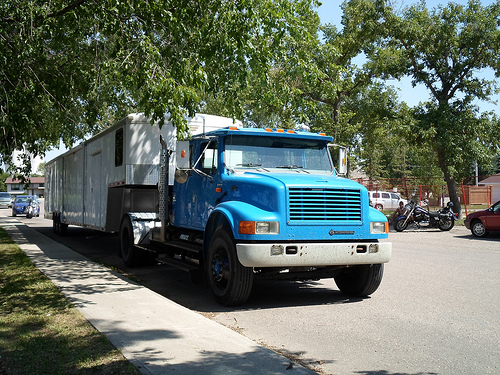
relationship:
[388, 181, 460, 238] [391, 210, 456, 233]
motorcycle has two wheels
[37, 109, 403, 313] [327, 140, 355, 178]
truck has side mirror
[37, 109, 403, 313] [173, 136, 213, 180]
truck has side mirror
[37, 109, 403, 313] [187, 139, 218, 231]
truck has passenger door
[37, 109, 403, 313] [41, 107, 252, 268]
truck has trailer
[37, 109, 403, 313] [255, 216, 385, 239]
truck has headlights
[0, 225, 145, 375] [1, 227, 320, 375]
grass beside sidewalk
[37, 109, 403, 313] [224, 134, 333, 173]
truck has windscreen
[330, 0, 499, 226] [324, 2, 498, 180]
tree has leaves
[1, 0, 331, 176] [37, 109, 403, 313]
leaves hanging above truck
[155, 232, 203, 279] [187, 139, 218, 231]
steps to passenger door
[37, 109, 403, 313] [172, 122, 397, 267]
truck has truck cab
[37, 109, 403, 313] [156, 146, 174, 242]
truck has smokestack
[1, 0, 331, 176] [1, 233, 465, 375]
leaves cast shadow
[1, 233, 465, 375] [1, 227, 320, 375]
shadow on sidewalk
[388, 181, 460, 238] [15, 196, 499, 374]
motorcycle parked on street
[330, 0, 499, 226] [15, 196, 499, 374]
tree beside street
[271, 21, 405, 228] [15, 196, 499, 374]
tree beside street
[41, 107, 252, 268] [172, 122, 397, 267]
trailer attached to truck cab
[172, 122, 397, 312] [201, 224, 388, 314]
truck cab has tires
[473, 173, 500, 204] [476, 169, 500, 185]
house has roof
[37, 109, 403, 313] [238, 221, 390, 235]
truck has turn signals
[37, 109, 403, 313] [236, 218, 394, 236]
truck has signal lights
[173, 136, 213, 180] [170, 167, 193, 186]
side mirror has attached mirror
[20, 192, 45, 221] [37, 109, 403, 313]
motorcycle behind truck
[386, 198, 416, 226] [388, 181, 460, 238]
man beside motorcycle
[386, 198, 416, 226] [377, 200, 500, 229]
man sitting on ground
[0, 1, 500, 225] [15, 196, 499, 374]
trees circumscribe street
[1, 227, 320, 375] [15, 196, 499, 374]
sidewalk beside street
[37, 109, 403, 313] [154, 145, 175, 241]
truck has exhaust pipe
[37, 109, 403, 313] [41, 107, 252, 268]
truck pulls trailer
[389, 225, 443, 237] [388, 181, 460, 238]
shadow of motorcycle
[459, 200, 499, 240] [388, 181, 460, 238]
car behind motorcycle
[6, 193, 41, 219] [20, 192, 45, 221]
car behind motorcycle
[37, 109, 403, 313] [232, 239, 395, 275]
truck has bumper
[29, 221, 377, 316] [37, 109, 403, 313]
shadow of truck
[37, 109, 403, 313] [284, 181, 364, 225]
truck has grille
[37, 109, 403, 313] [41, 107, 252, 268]
truck tows trailer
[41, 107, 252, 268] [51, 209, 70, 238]
trailer has back wheels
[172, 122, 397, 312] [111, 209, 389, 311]
truck cab has four wheels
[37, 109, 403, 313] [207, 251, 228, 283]
truck has hubcap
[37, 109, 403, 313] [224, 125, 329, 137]
truck has clearance lights